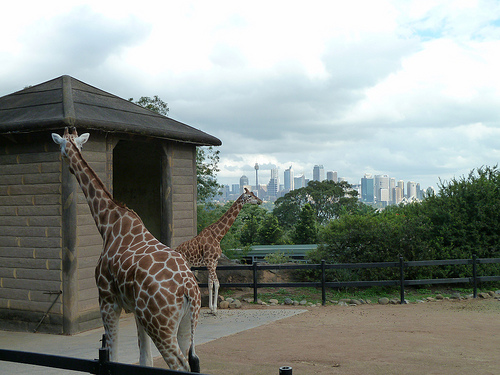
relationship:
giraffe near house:
[53, 126, 203, 371] [1, 74, 225, 334]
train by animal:
[228, 242, 318, 262] [175, 188, 261, 308]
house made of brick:
[1, 73, 220, 334] [28, 190, 62, 203]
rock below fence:
[267, 295, 278, 305] [186, 257, 491, 300]